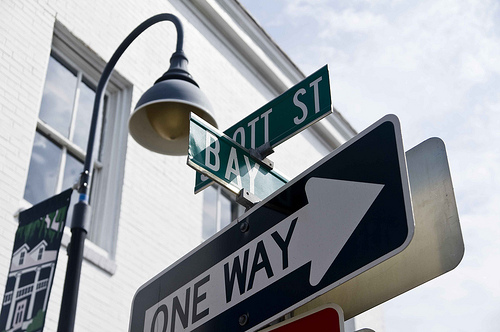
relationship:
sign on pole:
[119, 92, 332, 212] [55, 12, 183, 331]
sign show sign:
[193, 62, 330, 194] [193, 62, 330, 194]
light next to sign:
[148, 103, 198, 150] [174, 64, 334, 184]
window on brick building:
[38, 47, 80, 142] [0, 0, 358, 330]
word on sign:
[202, 126, 262, 200] [176, 100, 302, 207]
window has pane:
[20, 15, 136, 259] [40, 37, 80, 137]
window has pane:
[20, 17, 145, 217] [71, 76, 100, 151]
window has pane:
[20, 15, 136, 259] [23, 128, 60, 208]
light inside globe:
[148, 103, 198, 140] [126, 52, 219, 156]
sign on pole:
[193, 62, 330, 194] [226, 190, 246, 226]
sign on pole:
[119, 171, 421, 322] [227, 194, 238, 221]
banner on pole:
[0, 187, 74, 331] [55, 57, 122, 329]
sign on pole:
[174, 111, 294, 205] [223, 201, 246, 215]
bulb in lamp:
[152, 114, 192, 141] [126, 61, 219, 156]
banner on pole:
[0, 174, 89, 319] [55, 12, 183, 331]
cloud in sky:
[236, 1, 500, 330] [235, 0, 497, 330]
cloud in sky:
[330, 37, 485, 127] [235, 0, 497, 330]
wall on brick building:
[125, 149, 198, 265] [0, 0, 358, 330]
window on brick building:
[20, 15, 136, 259] [1, 0, 392, 330]